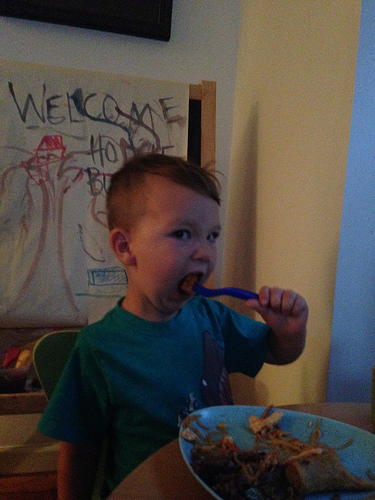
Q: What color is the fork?
A: Blue.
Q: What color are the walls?
A: White.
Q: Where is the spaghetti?
A: On the plate.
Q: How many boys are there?
A: One.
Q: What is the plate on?
A: The table.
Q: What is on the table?
A: The plate.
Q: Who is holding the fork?
A: The boy.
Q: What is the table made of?
A: Wood.